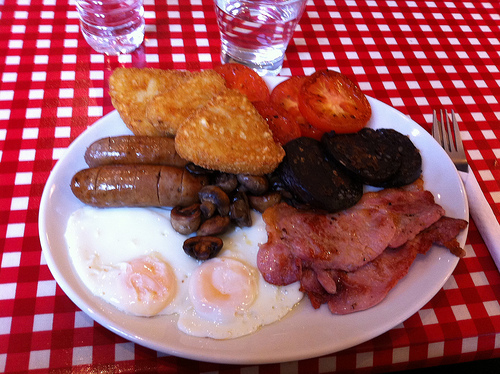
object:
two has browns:
[108, 61, 283, 174]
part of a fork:
[427, 108, 470, 175]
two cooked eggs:
[66, 198, 304, 341]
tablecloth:
[1, 1, 499, 373]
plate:
[34, 74, 470, 365]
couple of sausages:
[68, 133, 201, 208]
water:
[216, 3, 296, 75]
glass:
[209, 0, 307, 77]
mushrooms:
[180, 234, 223, 262]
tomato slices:
[296, 70, 370, 134]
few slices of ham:
[259, 181, 468, 320]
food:
[269, 135, 363, 214]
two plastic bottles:
[66, 1, 309, 77]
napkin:
[454, 167, 499, 268]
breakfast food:
[172, 93, 286, 176]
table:
[0, 0, 499, 373]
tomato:
[210, 65, 267, 103]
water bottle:
[73, 0, 148, 56]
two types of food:
[70, 95, 284, 211]